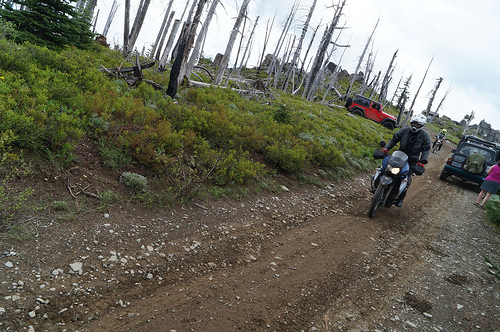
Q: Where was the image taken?
A: It was taken at the road.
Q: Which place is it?
A: It is a road.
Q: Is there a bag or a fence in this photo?
A: No, there are no fences or bags.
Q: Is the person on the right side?
A: Yes, the person is on the right of the image.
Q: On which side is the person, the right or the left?
A: The person is on the right of the image.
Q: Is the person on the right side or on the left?
A: The person is on the right of the image.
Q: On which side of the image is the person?
A: The person is on the right of the image.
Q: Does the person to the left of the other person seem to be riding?
A: Yes, the person is riding.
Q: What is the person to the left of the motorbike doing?
A: The person is riding.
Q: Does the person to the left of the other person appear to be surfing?
A: No, the person is riding.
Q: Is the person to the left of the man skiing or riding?
A: The person is riding.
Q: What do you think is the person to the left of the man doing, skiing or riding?
A: The person is riding.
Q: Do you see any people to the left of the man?
A: Yes, there is a person to the left of the man.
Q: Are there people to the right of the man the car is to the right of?
A: No, the person is to the left of the man.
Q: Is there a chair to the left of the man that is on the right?
A: No, there is a person to the left of the man.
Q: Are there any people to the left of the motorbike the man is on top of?
A: Yes, there is a person to the left of the motorbike.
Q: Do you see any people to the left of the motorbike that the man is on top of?
A: Yes, there is a person to the left of the motorbike.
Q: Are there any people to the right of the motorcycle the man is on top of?
A: No, the person is to the left of the motorbike.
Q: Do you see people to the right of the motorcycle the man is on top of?
A: No, the person is to the left of the motorbike.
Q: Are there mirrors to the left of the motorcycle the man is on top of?
A: No, there is a person to the left of the motorcycle.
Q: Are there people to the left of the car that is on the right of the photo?
A: Yes, there is a person to the left of the car.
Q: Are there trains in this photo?
A: No, there are no trains.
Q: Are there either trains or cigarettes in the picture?
A: No, there are no trains or cigarettes.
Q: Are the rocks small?
A: Yes, the rocks are small.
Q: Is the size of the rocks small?
A: Yes, the rocks are small.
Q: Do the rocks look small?
A: Yes, the rocks are small.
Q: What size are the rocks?
A: The rocks are small.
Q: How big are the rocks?
A: The rocks are small.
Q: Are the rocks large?
A: No, the rocks are small.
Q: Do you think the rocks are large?
A: No, the rocks are small.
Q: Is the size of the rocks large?
A: No, the rocks are small.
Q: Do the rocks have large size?
A: No, the rocks are small.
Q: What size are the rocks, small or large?
A: The rocks are small.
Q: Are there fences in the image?
A: No, there are no fences.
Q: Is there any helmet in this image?
A: Yes, there is a helmet.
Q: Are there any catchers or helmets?
A: Yes, there is a helmet.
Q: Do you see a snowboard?
A: No, there are no snowboards.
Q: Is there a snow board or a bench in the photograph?
A: No, there are no snowboards or benches.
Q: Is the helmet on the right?
A: Yes, the helmet is on the right of the image.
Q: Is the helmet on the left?
A: No, the helmet is on the right of the image.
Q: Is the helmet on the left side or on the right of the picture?
A: The helmet is on the right of the image.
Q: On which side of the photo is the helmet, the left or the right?
A: The helmet is on the right of the image.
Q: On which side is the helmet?
A: The helmet is on the right of the image.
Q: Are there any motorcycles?
A: Yes, there is a motorcycle.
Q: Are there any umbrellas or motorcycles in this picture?
A: Yes, there is a motorcycle.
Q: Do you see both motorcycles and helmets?
A: Yes, there are both a motorcycle and a helmet.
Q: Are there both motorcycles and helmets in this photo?
A: Yes, there are both a motorcycle and a helmet.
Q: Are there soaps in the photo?
A: No, there are no soaps.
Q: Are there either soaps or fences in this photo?
A: No, there are no soaps or fences.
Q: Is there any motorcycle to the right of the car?
A: No, the motorcycle is to the left of the car.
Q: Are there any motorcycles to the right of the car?
A: No, the motorcycle is to the left of the car.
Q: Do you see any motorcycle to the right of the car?
A: No, the motorcycle is to the left of the car.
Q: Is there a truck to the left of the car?
A: No, there is a motorcycle to the left of the car.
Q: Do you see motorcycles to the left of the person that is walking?
A: Yes, there is a motorcycle to the left of the person.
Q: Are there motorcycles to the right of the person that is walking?
A: No, the motorcycle is to the left of the person.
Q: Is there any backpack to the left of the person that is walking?
A: No, there is a motorcycle to the left of the person.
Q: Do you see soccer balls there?
A: No, there are no soccer balls.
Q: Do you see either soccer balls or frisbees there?
A: No, there are no soccer balls or frisbees.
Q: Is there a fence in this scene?
A: No, there are no fences.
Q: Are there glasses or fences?
A: No, there are no fences or glasses.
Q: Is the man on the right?
A: Yes, the man is on the right of the image.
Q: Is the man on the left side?
A: No, the man is on the right of the image.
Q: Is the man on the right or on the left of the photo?
A: The man is on the right of the image.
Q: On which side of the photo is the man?
A: The man is on the right of the image.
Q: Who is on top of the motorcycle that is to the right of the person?
A: The man is on top of the motorbike.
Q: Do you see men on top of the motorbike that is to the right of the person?
A: Yes, there is a man on top of the motorbike.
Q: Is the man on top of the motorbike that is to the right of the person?
A: Yes, the man is on top of the motorbike.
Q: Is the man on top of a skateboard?
A: No, the man is on top of the motorbike.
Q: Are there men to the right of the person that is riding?
A: Yes, there is a man to the right of the person.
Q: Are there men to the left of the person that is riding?
A: No, the man is to the right of the person.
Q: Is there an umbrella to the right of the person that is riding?
A: No, there is a man to the right of the person.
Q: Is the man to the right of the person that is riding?
A: Yes, the man is to the right of the person.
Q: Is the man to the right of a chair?
A: No, the man is to the right of the person.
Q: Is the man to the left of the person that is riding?
A: No, the man is to the right of the person.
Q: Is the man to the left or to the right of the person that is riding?
A: The man is to the right of the person.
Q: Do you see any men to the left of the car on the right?
A: Yes, there is a man to the left of the car.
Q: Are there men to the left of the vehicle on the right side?
A: Yes, there is a man to the left of the car.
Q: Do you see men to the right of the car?
A: No, the man is to the left of the car.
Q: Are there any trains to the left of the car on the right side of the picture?
A: No, there is a man to the left of the car.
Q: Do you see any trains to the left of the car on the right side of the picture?
A: No, there is a man to the left of the car.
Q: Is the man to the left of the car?
A: Yes, the man is to the left of the car.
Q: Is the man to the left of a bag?
A: No, the man is to the left of the car.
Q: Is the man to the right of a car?
A: No, the man is to the left of a car.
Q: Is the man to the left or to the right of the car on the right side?
A: The man is to the left of the car.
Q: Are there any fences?
A: No, there are no fences.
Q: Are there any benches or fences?
A: No, there are no fences or benches.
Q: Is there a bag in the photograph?
A: No, there are no bags.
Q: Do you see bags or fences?
A: No, there are no bags or fences.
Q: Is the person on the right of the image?
A: Yes, the person is on the right of the image.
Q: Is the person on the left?
A: No, the person is on the right of the image.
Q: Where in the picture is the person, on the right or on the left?
A: The person is on the right of the image.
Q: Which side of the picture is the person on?
A: The person is on the right of the image.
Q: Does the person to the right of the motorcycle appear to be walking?
A: Yes, the person is walking.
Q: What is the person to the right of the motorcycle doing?
A: The person is walking.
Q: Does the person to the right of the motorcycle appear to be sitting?
A: No, the person is walking.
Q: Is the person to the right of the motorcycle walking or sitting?
A: The person is walking.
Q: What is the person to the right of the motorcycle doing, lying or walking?
A: The person is walking.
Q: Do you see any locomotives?
A: No, there are no locomotives.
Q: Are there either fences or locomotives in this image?
A: No, there are no locomotives or fences.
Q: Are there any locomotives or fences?
A: No, there are no locomotives or fences.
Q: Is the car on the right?
A: Yes, the car is on the right of the image.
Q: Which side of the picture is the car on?
A: The car is on the right of the image.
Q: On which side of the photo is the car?
A: The car is on the right of the image.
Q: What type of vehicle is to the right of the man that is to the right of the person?
A: The vehicle is a car.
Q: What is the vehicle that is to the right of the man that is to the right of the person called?
A: The vehicle is a car.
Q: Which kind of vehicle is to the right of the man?
A: The vehicle is a car.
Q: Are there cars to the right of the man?
A: Yes, there is a car to the right of the man.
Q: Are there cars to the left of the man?
A: No, the car is to the right of the man.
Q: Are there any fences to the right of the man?
A: No, there is a car to the right of the man.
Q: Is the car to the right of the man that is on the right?
A: Yes, the car is to the right of the man.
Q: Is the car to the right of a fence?
A: No, the car is to the right of the man.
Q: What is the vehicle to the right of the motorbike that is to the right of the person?
A: The vehicle is a car.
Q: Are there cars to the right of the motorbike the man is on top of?
A: Yes, there is a car to the right of the motorcycle.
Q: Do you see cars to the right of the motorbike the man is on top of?
A: Yes, there is a car to the right of the motorcycle.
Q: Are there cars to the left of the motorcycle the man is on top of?
A: No, the car is to the right of the motorbike.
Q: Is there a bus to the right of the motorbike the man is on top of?
A: No, there is a car to the right of the motorcycle.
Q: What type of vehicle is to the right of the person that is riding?
A: The vehicle is a car.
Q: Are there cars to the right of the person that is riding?
A: Yes, there is a car to the right of the person.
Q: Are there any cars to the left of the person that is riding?
A: No, the car is to the right of the person.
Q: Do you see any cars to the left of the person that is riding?
A: No, the car is to the right of the person.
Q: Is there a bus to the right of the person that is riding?
A: No, there is a car to the right of the person.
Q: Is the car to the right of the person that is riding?
A: Yes, the car is to the right of the person.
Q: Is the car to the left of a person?
A: No, the car is to the right of a person.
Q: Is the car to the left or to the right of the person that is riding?
A: The car is to the right of the person.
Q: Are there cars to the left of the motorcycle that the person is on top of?
A: No, the car is to the right of the motorcycle.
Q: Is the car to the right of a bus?
A: No, the car is to the right of the motorbike.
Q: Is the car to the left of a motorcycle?
A: No, the car is to the right of a motorcycle.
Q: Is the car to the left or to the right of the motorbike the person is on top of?
A: The car is to the right of the motorbike.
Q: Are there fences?
A: No, there are no fences.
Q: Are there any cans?
A: No, there are no cans.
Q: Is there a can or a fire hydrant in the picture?
A: No, there are no cans or fire hydrants.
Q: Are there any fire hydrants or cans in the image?
A: No, there are no cans or fire hydrants.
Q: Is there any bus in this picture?
A: No, there are no buses.